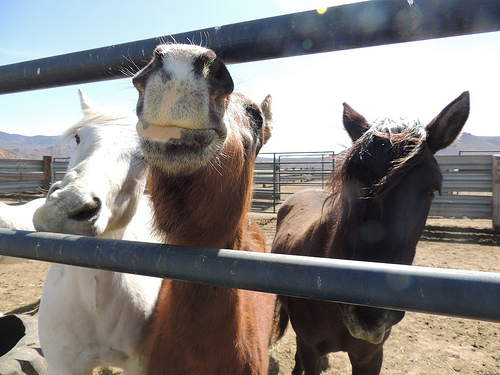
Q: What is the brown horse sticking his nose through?
A: A fence.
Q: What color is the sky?
A: Blue.